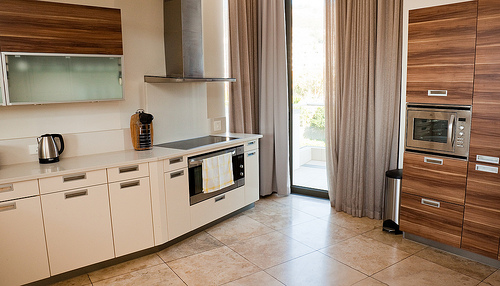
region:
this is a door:
[246, 5, 400, 222]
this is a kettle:
[23, 125, 76, 171]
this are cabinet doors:
[35, 175, 110, 275]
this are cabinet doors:
[400, 137, 465, 205]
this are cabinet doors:
[393, 177, 465, 253]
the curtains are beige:
[229, 3, 399, 223]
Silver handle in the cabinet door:
[412, 198, 443, 210]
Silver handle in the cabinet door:
[470, 147, 496, 164]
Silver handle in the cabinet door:
[472, 158, 497, 176]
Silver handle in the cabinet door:
[116, 175, 141, 187]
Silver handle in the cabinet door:
[61, 188, 91, 198]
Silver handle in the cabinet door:
[0, 200, 16, 216]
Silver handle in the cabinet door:
[60, 171, 92, 183]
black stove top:
[151, 128, 246, 155]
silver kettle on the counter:
[33, 130, 68, 167]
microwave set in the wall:
[404, 98, 473, 161]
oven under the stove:
[186, 142, 248, 207]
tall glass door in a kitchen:
[285, 0, 333, 197]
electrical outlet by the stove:
[209, 117, 226, 131]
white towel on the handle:
[200, 147, 238, 195]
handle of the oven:
[188, 148, 238, 165]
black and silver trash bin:
[378, 163, 405, 238]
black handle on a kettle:
[54, 132, 64, 152]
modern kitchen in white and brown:
[9, 10, 491, 280]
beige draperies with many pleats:
[225, 3, 400, 220]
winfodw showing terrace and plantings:
[288, 1, 330, 195]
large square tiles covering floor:
[43, 185, 493, 280]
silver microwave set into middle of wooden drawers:
[395, 0, 479, 259]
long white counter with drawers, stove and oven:
[3, 129, 263, 281]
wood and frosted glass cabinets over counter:
[3, 2, 130, 173]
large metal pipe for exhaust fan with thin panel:
[137, 2, 236, 87]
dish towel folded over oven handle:
[181, 139, 251, 205]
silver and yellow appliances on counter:
[33, 105, 158, 167]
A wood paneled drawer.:
[403, 5, 491, 104]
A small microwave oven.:
[396, 95, 483, 158]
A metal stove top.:
[152, 130, 292, 230]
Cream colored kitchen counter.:
[4, 130, 252, 265]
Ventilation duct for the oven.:
[141, 3, 279, 101]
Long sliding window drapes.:
[324, 3, 397, 219]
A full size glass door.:
[287, 0, 339, 212]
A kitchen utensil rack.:
[122, 110, 158, 155]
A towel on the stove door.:
[195, 147, 250, 198]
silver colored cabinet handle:
[423, 156, 443, 167]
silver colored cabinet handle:
[426, 88, 448, 98]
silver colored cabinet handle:
[475, 152, 498, 163]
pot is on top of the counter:
[34, 133, 64, 162]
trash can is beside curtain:
[383, 170, 402, 235]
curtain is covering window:
[227, 0, 404, 217]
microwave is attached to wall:
[406, 99, 471, 162]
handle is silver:
[118, 162, 139, 174]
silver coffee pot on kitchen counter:
[30, 128, 70, 167]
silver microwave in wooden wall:
[398, 99, 476, 167]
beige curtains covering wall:
[223, 0, 405, 222]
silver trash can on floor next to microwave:
[378, 165, 404, 239]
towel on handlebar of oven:
[195, 148, 240, 198]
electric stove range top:
[152, 130, 241, 152]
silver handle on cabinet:
[60, 185, 92, 202]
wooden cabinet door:
[401, 1, 483, 111]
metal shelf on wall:
[139, 68, 239, 88]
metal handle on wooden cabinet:
[423, 83, 451, 102]